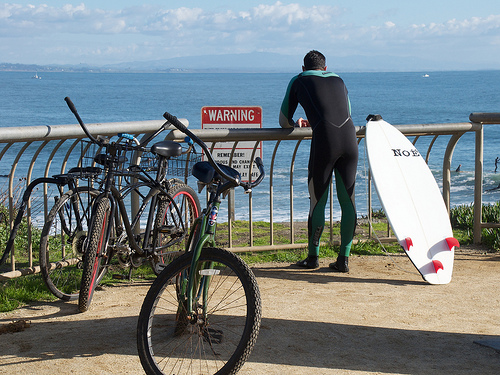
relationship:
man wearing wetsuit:
[279, 49, 359, 274] [279, 69, 359, 258]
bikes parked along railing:
[42, 95, 252, 372] [0, 110, 494, 276]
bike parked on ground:
[139, 151, 260, 373] [0, 245, 499, 373]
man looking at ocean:
[279, 49, 359, 274] [2, 68, 499, 236]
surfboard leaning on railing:
[355, 109, 467, 301] [0, 119, 493, 268]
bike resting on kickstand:
[139, 151, 260, 288] [196, 317, 221, 357]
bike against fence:
[69, 119, 207, 311] [0, 110, 498, 286]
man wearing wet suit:
[279, 49, 359, 274] [282, 70, 354, 270]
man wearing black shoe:
[279, 49, 359, 274] [289, 254, 319, 268]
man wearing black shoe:
[279, 49, 359, 274] [327, 257, 348, 272]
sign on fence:
[195, 103, 270, 186] [11, 115, 498, 267]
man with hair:
[279, 49, 359, 274] [302, 47, 324, 67]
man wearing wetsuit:
[279, 49, 359, 274] [297, 72, 365, 172]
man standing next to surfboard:
[279, 49, 359, 274] [366, 111, 463, 286]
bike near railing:
[139, 151, 260, 373] [3, 120, 489, 249]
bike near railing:
[69, 94, 167, 311] [3, 120, 489, 249]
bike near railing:
[18, 142, 195, 282] [3, 120, 489, 249]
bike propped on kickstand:
[139, 151, 260, 373] [200, 319, 225, 357]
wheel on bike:
[89, 213, 113, 270] [75, 117, 128, 296]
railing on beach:
[71, 103, 496, 255] [31, 45, 463, 356]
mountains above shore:
[105, 37, 240, 97] [1, 60, 477, 70]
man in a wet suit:
[279, 49, 359, 274] [276, 71, 360, 276]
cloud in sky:
[1, 2, 500, 39] [1, 0, 498, 70]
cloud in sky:
[1, 2, 71, 39] [1, 0, 498, 70]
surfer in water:
[491, 151, 499, 179] [383, 88, 494, 204]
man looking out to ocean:
[279, 49, 359, 274] [2, 68, 499, 236]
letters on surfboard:
[389, 149, 429, 163] [366, 111, 463, 286]